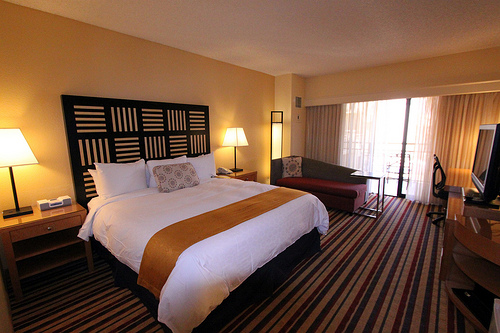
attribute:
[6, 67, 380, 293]
suite — luxury, scene, bedroom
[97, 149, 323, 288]
bed — beautiful, white, king size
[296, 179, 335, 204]
chair — here, swiveling, black, red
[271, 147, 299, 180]
pillow — printed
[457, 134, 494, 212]
television — flat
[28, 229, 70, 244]
box — tissue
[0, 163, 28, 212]
lamps — bedside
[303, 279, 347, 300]
carpeting — floor, beige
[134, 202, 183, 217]
bedspread — white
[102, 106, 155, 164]
headboard — black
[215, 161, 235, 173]
phone — landline, white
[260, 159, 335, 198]
couch — here, red